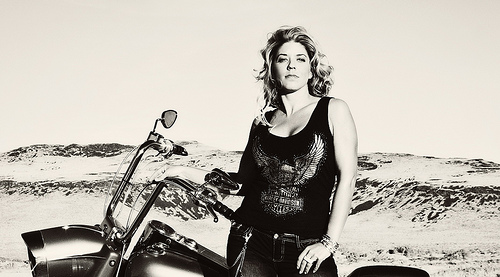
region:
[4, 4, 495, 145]
light of daytime sky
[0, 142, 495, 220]
snow on rocky hill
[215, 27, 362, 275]
woman posing for photo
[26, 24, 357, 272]
standing woman and motorcycle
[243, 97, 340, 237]
tank top with eagle design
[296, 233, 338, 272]
shiny bracelets on wrist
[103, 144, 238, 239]
tall handlebars on bike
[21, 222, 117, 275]
cover of front light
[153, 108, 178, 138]
side mirror on handlebar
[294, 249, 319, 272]
ring on woman's finger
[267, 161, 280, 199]
part of a shirt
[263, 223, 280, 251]
part of a belt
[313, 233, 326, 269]
part of a finger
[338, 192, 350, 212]
part of an arm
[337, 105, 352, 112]
part of a shoulder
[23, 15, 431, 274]
a woman by a motorcycle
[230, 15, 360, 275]
a woman with blonde hair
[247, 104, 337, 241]
a Harley- Davidson shirt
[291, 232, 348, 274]
a hand with a bracelet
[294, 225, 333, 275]
a hand wearing rings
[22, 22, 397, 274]
a woman standing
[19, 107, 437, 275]
a shiny motorcycle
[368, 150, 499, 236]
mountains in the distance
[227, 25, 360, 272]
a woman staring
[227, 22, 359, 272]
a woman waiting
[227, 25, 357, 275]
Woman wearing all black.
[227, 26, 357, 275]
Blonde woman standing in the desert.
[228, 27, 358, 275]
Woman in all black standing next to a motorcycle.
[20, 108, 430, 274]
Silver motorcycle behind a woman.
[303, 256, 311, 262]
Ring on blond woman's fingers.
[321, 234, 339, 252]
Bracelets on woman wrist.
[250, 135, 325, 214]
Eagle on a black tank top shirt.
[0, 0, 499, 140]
Clear sky in the background.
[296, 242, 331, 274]
Woman's hand on her hip.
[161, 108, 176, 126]
Motorcycle rear view mirror.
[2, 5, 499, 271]
Black and white shot, daytime, likely, with indistinct landscape.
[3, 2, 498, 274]
Close view of person and vehicle, against indistinct backdrop.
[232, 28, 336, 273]
Standing woman, with hand near hip.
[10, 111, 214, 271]
Motorcycle, behind woman.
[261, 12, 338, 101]
Head, with blonde, shoulder length hair.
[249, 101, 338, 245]
Black tank, with eagle, showing cleavage.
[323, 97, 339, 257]
Muscular arm, with bracelets.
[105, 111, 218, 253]
Tall, chrome handlebars, with mirror.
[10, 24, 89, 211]
Pale sky, overtopping uneven terrain, possibly mountainous.